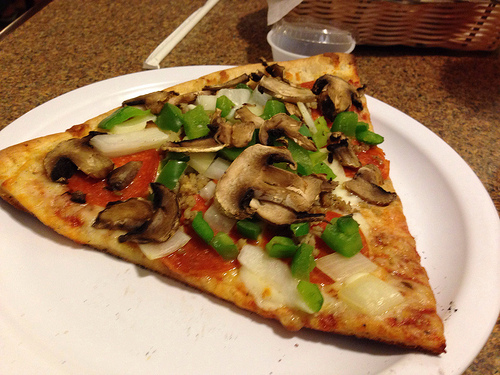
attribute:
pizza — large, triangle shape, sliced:
[2, 50, 447, 358]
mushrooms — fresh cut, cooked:
[209, 138, 314, 220]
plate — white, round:
[1, 65, 500, 374]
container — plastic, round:
[265, 27, 356, 62]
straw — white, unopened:
[140, 0, 224, 70]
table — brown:
[1, 1, 500, 374]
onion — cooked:
[335, 273, 405, 320]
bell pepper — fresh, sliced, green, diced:
[321, 217, 364, 258]